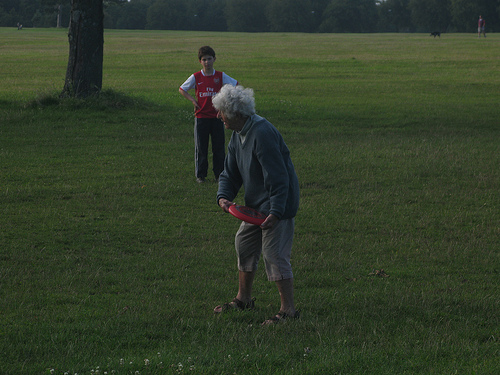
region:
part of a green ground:
[367, 187, 422, 237]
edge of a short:
[258, 265, 284, 294]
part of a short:
[265, 242, 288, 271]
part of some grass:
[356, 305, 416, 372]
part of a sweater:
[259, 153, 299, 217]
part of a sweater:
[246, 236, 277, 271]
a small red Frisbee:
[225, 202, 270, 224]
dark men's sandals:
[207, 295, 257, 316]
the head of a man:
[205, 85, 257, 130]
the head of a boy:
[194, 42, 219, 74]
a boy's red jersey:
[189, 70, 226, 111]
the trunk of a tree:
[60, 2, 110, 97]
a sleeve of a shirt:
[222, 71, 239, 88]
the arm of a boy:
[171, 73, 204, 109]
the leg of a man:
[257, 220, 299, 311]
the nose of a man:
[213, 112, 222, 119]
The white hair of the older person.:
[213, 74, 261, 120]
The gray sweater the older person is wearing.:
[208, 128, 303, 220]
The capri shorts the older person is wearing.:
[233, 211, 290, 277]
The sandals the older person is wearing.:
[208, 292, 301, 326]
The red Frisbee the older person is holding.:
[227, 201, 265, 232]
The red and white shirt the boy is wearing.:
[188, 52, 230, 114]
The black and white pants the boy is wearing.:
[189, 114, 229, 178]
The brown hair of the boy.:
[197, 38, 212, 61]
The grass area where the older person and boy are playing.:
[75, 129, 415, 373]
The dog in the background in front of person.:
[416, 22, 452, 48]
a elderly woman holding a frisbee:
[191, 57, 309, 325]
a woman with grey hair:
[198, 77, 273, 137]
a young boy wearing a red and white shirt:
[167, 45, 233, 118]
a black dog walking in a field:
[418, 10, 458, 49]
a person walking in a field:
[470, 7, 491, 41]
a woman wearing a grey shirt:
[204, 75, 297, 224]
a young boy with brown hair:
[178, 40, 225, 77]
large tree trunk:
[26, 8, 138, 116]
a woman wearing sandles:
[188, 97, 293, 366]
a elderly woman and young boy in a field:
[144, 30, 319, 313]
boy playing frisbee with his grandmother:
[175, 42, 253, 190]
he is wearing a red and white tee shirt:
[178, 68, 243, 122]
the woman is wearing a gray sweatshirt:
[204, 82, 325, 337]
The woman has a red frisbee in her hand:
[228, 201, 266, 233]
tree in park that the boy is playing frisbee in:
[44, 0, 119, 115]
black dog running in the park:
[426, 28, 443, 42]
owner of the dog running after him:
[472, 16, 487, 39]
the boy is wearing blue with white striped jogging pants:
[190, 113, 231, 189]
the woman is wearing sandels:
[208, 290, 259, 320]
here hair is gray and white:
[211, 85, 264, 125]